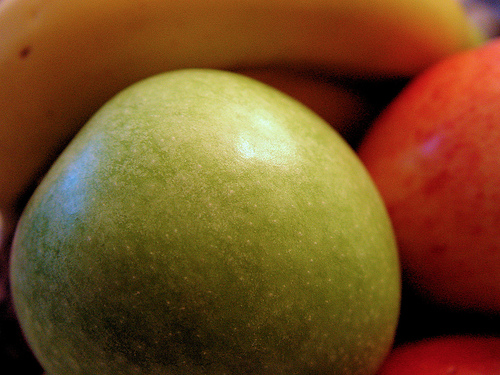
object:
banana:
[0, 0, 487, 244]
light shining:
[423, 135, 439, 155]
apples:
[6, 62, 403, 373]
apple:
[354, 37, 499, 312]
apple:
[8, 67, 401, 374]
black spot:
[17, 41, 35, 59]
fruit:
[377, 335, 498, 374]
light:
[228, 112, 298, 170]